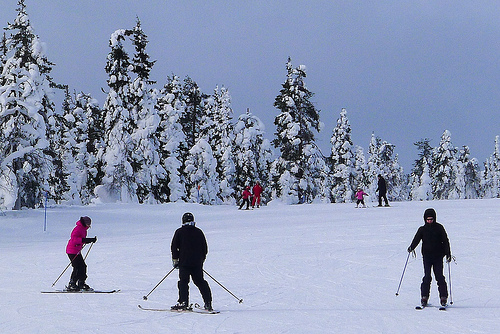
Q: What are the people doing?
A: Skiing.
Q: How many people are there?
A: 7.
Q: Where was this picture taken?
A: Ski resort.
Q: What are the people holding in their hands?
A: Ski poles.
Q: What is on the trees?
A: Snow.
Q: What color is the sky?
A: Blue.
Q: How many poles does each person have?
A: 2.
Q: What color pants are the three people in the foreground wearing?
A: Black.